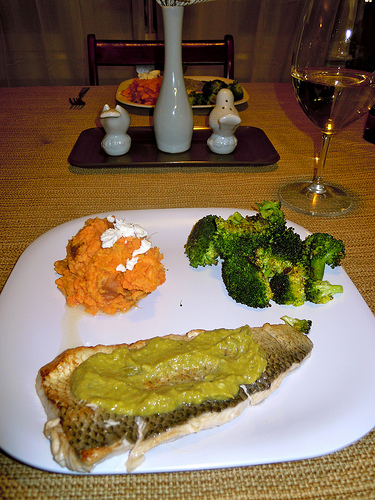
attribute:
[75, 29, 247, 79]
chair — brown, wooden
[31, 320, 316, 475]
fish — served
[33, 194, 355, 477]
meal — served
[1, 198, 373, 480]
plate — part, white, edge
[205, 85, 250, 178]
bird — porcelain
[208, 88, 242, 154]
bird — salt shaker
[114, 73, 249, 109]
plate — across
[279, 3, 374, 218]
glass — half-full, wine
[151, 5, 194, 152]
porcelain vase — white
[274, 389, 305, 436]
plate — part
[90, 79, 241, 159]
shakers — salt, pepper